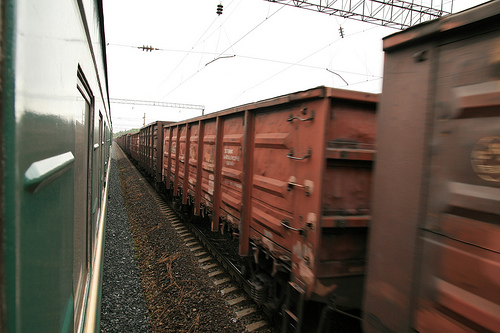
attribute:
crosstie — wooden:
[181, 240, 201, 246]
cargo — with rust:
[224, 91, 368, 301]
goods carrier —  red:
[162, 107, 349, 288]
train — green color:
[21, 6, 172, 317]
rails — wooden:
[108, 143, 267, 332]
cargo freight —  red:
[160, 71, 370, 308]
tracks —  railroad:
[118, 142, 345, 324]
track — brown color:
[112, 138, 291, 331]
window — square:
[77, 87, 87, 332]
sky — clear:
[102, 0, 494, 134]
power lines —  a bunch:
[114, 11, 267, 113]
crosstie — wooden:
[195, 247, 206, 255]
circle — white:
[185, 146, 197, 163]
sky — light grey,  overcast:
[117, 9, 325, 87]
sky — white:
[158, 15, 263, 49]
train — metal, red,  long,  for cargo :
[113, 0, 499, 330]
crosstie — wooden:
[223, 292, 247, 309]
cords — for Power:
[90, 40, 239, 58]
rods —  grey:
[264, 3, 459, 32]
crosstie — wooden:
[205, 278, 232, 289]